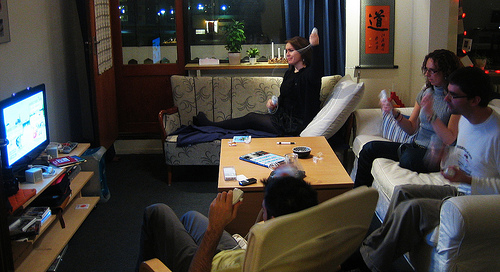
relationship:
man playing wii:
[362, 63, 500, 272] [0, 56, 144, 242]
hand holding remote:
[368, 91, 403, 119] [379, 82, 405, 104]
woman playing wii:
[358, 41, 448, 174] [0, 56, 144, 242]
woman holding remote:
[358, 41, 448, 174] [379, 82, 405, 104]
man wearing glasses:
[394, 71, 493, 268] [433, 87, 462, 106]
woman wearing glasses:
[358, 41, 448, 174] [417, 61, 446, 76]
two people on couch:
[349, 36, 494, 246] [255, 41, 490, 270]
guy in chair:
[161, 172, 337, 271] [229, 180, 384, 270]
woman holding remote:
[358, 41, 448, 174] [377, 88, 393, 113]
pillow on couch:
[367, 109, 417, 140] [255, 41, 490, 270]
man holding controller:
[394, 71, 493, 268] [432, 149, 465, 189]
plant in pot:
[242, 39, 266, 65] [247, 55, 262, 67]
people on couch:
[394, 71, 493, 268] [255, 41, 490, 270]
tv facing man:
[0, 69, 69, 166] [362, 63, 500, 272]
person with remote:
[358, 41, 448, 174] [379, 82, 405, 104]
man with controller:
[362, 63, 500, 272] [439, 146, 468, 179]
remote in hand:
[379, 82, 405, 104] [368, 91, 403, 119]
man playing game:
[362, 63, 500, 272] [341, 80, 476, 186]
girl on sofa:
[169, 20, 330, 138] [145, 71, 367, 150]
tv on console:
[0, 69, 69, 166] [3, 125, 111, 271]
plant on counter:
[242, 39, 266, 65] [144, 62, 279, 91]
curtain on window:
[262, 4, 364, 92] [110, 0, 348, 97]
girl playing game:
[358, 41, 448, 174] [1, 77, 52, 180]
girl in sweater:
[169, 20, 330, 138] [261, 66, 324, 139]